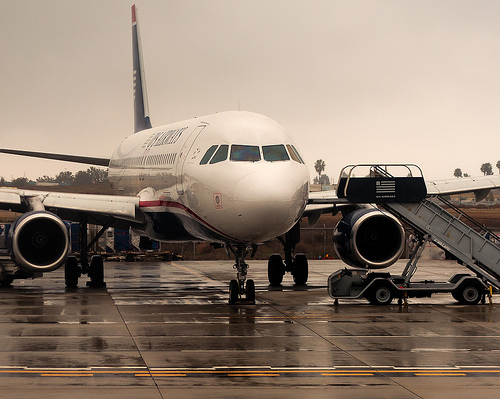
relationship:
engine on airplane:
[9, 210, 71, 274] [0, 4, 500, 302]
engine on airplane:
[6, 189, 79, 276] [0, 4, 500, 302]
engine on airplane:
[337, 196, 410, 267] [0, 4, 500, 302]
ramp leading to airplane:
[370, 163, 500, 290] [0, 4, 500, 302]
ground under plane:
[1, 274, 498, 396] [121, 119, 349, 262]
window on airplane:
[229, 141, 261, 164] [0, 4, 500, 302]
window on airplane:
[260, 140, 289, 160] [0, 4, 500, 302]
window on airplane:
[196, 140, 216, 163] [0, 4, 500, 302]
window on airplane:
[211, 138, 230, 165] [0, 4, 500, 302]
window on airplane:
[289, 140, 301, 163] [0, 4, 500, 302]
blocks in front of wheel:
[228, 295, 261, 309] [261, 250, 317, 293]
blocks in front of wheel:
[83, 275, 109, 290] [57, 248, 111, 297]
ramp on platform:
[384, 158, 484, 284] [89, 230, 267, 395]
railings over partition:
[335, 153, 429, 182] [342, 171, 428, 201]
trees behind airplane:
[0, 166, 109, 186] [0, 4, 500, 302]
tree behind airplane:
[450, 163, 495, 199] [0, 4, 500, 302]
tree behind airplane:
[315, 158, 326, 185] [0, 4, 500, 302]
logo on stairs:
[376, 174, 395, 199] [338, 150, 499, 285]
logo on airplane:
[141, 122, 193, 149] [0, 4, 500, 302]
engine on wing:
[9, 210, 71, 274] [0, 177, 161, 223]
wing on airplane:
[0, 177, 161, 223] [0, 4, 500, 302]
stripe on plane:
[140, 182, 199, 232] [41, 79, 376, 309]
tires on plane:
[63, 254, 105, 293] [70, 39, 413, 300]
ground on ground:
[1, 274, 498, 396] [1, 179, 498, 396]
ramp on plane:
[370, 163, 500, 290] [2, 3, 406, 308]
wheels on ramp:
[326, 267, 486, 305] [370, 163, 500, 290]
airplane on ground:
[0, 4, 500, 302] [0, 205, 497, 397]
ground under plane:
[1, 274, 498, 396] [86, 69, 369, 306]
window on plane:
[262, 144, 290, 161] [99, 70, 385, 329]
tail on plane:
[114, 14, 166, 132] [19, 5, 454, 350]